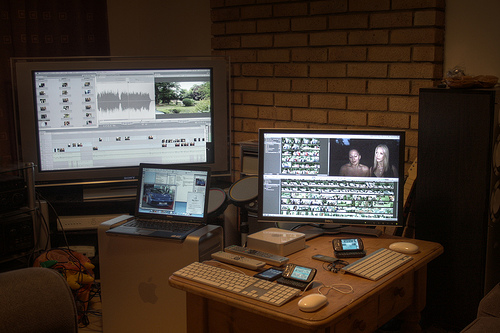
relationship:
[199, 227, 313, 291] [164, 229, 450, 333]
remotes on desk